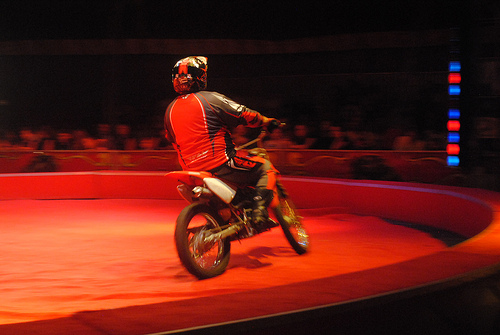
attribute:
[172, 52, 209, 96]
helmet — red, black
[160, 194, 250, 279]
tire — back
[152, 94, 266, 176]
shirt — red, black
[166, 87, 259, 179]
jacket — black, red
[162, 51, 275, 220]
man — motorcross bike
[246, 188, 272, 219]
motocross boot — black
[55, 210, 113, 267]
pit — red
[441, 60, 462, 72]
light — blue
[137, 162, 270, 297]
wheel — rear